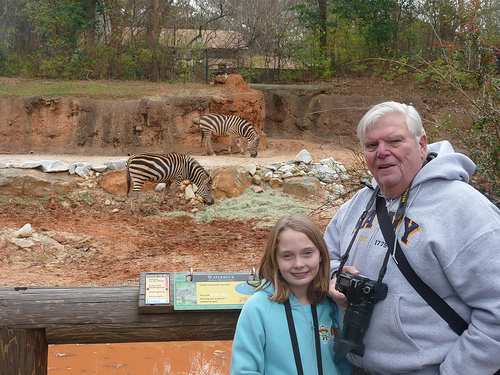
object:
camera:
[334, 182, 409, 359]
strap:
[335, 182, 408, 279]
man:
[325, 101, 500, 374]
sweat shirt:
[321, 140, 497, 375]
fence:
[2, 284, 269, 375]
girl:
[232, 218, 344, 375]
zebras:
[124, 112, 262, 215]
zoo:
[4, 4, 495, 233]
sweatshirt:
[230, 285, 349, 375]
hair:
[354, 98, 427, 144]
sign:
[139, 266, 261, 315]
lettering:
[345, 205, 421, 250]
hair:
[251, 213, 332, 308]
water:
[5, 252, 236, 373]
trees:
[95, 2, 310, 85]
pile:
[243, 146, 350, 186]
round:
[0, 278, 246, 374]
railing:
[1, 285, 247, 341]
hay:
[134, 207, 255, 259]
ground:
[5, 138, 373, 268]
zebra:
[122, 147, 215, 212]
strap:
[277, 291, 325, 375]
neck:
[284, 280, 319, 307]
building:
[113, 21, 249, 77]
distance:
[8, 31, 500, 96]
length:
[254, 219, 333, 311]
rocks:
[222, 139, 344, 187]